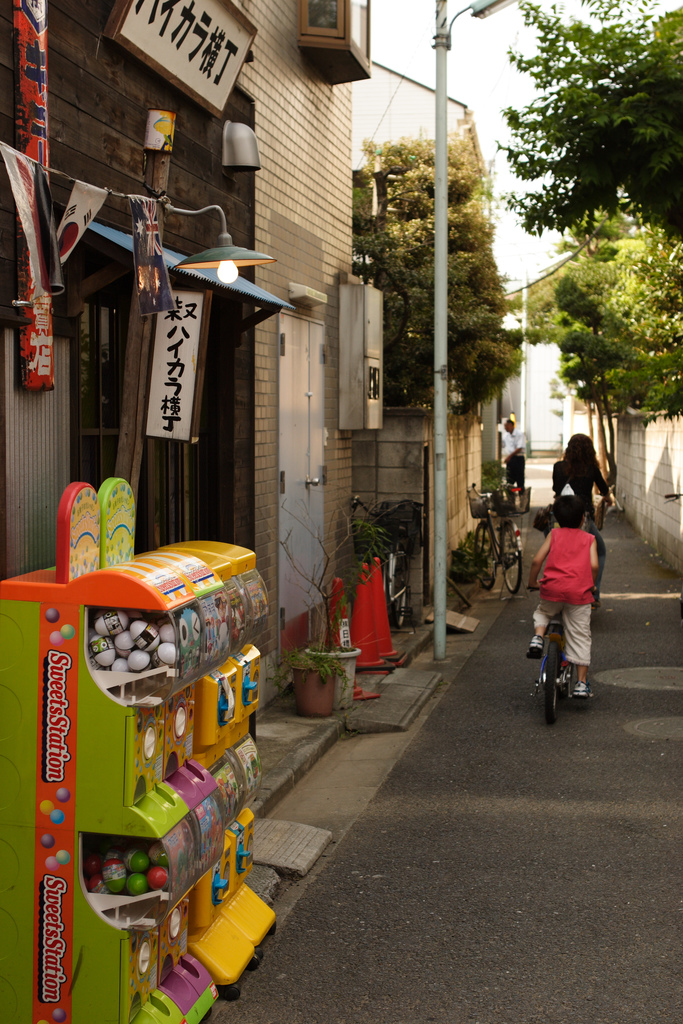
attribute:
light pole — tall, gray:
[428, 1, 517, 664]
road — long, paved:
[198, 455, 662, 1015]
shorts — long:
[527, 594, 595, 669]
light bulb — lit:
[212, 253, 246, 296]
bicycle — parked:
[507, 614, 611, 708]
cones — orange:
[281, 538, 405, 706]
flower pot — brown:
[302, 646, 360, 737]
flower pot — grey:
[326, 644, 376, 698]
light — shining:
[599, 583, 682, 605]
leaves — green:
[396, 223, 420, 278]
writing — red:
[39, 643, 71, 784]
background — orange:
[33, 604, 76, 1017]